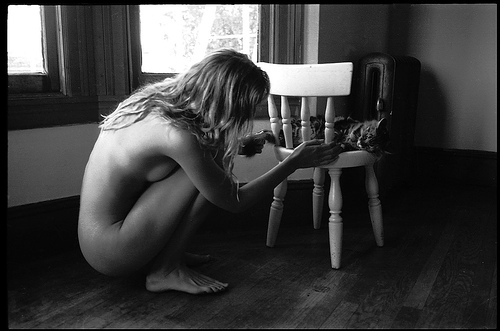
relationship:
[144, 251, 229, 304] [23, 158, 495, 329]
foot on floor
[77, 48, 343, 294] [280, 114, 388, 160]
lady petting cat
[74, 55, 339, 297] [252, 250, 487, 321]
lady on floor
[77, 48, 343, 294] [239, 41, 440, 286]
lady touches chair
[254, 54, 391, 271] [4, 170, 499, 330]
chair on floor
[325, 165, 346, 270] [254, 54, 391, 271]
leg on chair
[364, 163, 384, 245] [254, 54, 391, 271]
leg on chair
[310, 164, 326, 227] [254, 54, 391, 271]
leg on chair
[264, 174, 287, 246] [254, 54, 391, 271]
leg on chair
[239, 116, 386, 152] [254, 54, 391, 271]
cat sleeps on chair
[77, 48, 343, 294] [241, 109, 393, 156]
lady near cat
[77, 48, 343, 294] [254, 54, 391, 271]
lady near chair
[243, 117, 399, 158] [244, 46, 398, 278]
cat lying on chair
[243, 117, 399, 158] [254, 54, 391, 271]
cat sleeping on chair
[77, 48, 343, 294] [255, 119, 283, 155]
lady playing with tail